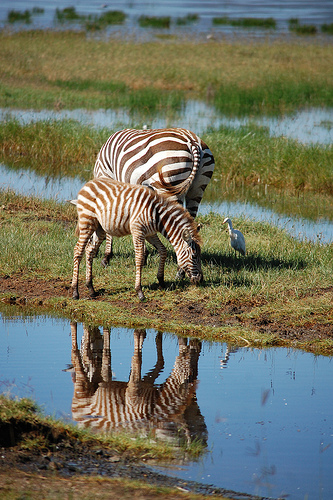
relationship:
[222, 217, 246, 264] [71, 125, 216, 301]
bird near cattle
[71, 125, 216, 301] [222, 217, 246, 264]
cattle near bird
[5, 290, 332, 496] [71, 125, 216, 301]
water near cattle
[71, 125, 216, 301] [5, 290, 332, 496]
cattle near water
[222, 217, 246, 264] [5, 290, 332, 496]
bird near water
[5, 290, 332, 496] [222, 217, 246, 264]
water near bird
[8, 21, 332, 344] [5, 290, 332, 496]
grass near water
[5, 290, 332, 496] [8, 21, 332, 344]
water near grass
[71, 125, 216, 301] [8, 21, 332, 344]
cattle on grass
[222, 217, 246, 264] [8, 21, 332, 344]
bird on grass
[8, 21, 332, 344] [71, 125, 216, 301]
grass under cattle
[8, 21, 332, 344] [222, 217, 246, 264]
grass under bird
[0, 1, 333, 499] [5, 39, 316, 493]
grass on ground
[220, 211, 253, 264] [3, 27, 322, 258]
bird on grass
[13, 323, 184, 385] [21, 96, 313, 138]
ripples on surface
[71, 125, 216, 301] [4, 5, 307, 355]
cattle grazing grass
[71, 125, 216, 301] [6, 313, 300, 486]
cattle next to water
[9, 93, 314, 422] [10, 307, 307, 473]
delta flooded water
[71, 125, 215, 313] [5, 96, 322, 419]
cattle standing area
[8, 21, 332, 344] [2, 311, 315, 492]
grass growing river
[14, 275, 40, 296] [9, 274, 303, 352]
mud on bank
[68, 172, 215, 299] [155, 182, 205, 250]
zebra has hair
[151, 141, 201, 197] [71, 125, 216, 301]
tail on cattle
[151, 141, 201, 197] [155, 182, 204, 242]
tail has hair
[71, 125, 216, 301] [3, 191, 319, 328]
cattle eating grass